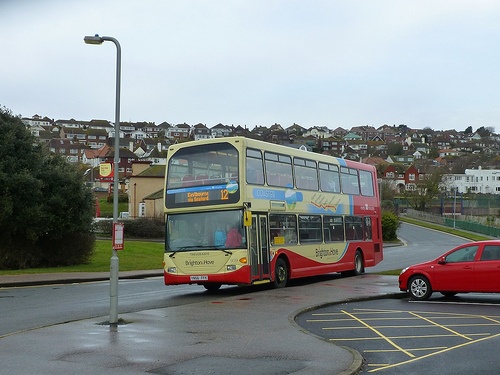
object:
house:
[386, 162, 418, 183]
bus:
[159, 135, 384, 294]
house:
[140, 137, 166, 149]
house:
[165, 127, 190, 139]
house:
[306, 125, 329, 138]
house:
[302, 128, 334, 139]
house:
[24, 113, 51, 131]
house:
[66, 124, 86, 138]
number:
[220, 189, 224, 200]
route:
[220, 189, 229, 201]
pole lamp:
[82, 33, 123, 322]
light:
[226, 264, 236, 270]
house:
[438, 149, 456, 157]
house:
[395, 155, 414, 162]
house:
[405, 132, 429, 144]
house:
[471, 132, 483, 139]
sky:
[0, 0, 500, 128]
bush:
[0, 103, 98, 271]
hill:
[25, 114, 498, 196]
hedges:
[93, 213, 167, 238]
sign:
[112, 222, 125, 251]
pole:
[109, 36, 122, 324]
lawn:
[0, 237, 165, 274]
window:
[245, 156, 265, 185]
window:
[165, 207, 247, 252]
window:
[246, 147, 263, 159]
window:
[265, 158, 295, 189]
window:
[294, 164, 319, 191]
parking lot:
[292, 292, 499, 374]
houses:
[104, 146, 138, 176]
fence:
[404, 208, 500, 239]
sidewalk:
[400, 219, 478, 243]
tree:
[1, 105, 98, 268]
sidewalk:
[0, 269, 163, 287]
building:
[127, 156, 164, 218]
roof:
[137, 164, 166, 178]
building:
[439, 166, 499, 196]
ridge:
[23, 116, 499, 204]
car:
[396, 238, 500, 302]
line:
[340, 309, 417, 358]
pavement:
[0, 274, 500, 375]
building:
[379, 164, 426, 193]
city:
[21, 113, 500, 220]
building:
[340, 147, 362, 162]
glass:
[246, 149, 262, 160]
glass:
[245, 157, 264, 184]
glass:
[319, 170, 341, 194]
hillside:
[24, 117, 134, 195]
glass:
[294, 166, 318, 191]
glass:
[166, 142, 240, 208]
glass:
[445, 245, 480, 264]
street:
[1, 220, 500, 375]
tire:
[408, 274, 434, 301]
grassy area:
[0, 240, 166, 276]